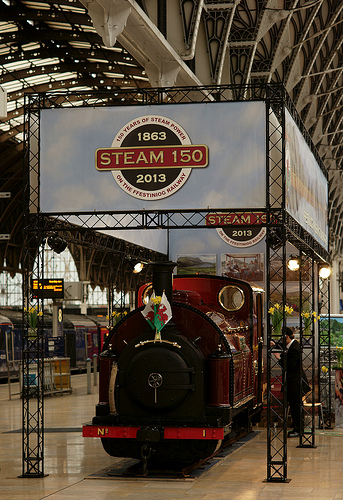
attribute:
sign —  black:
[31, 275, 66, 302]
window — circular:
[218, 285, 248, 309]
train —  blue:
[80, 268, 260, 498]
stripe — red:
[79, 421, 226, 444]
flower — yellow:
[285, 305, 297, 314]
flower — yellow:
[283, 305, 289, 314]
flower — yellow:
[271, 302, 285, 311]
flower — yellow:
[266, 306, 275, 317]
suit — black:
[281, 343, 311, 428]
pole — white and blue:
[84, 357, 91, 395]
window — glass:
[1, 238, 161, 310]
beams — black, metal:
[269, 210, 330, 267]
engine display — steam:
[16, 84, 290, 480]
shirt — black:
[269, 352, 300, 423]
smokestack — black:
[87, 271, 195, 453]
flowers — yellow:
[107, 309, 194, 455]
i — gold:
[201, 427, 205, 438]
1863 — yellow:
[134, 127, 167, 145]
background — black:
[118, 124, 179, 186]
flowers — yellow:
[264, 298, 328, 340]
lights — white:
[285, 250, 332, 279]